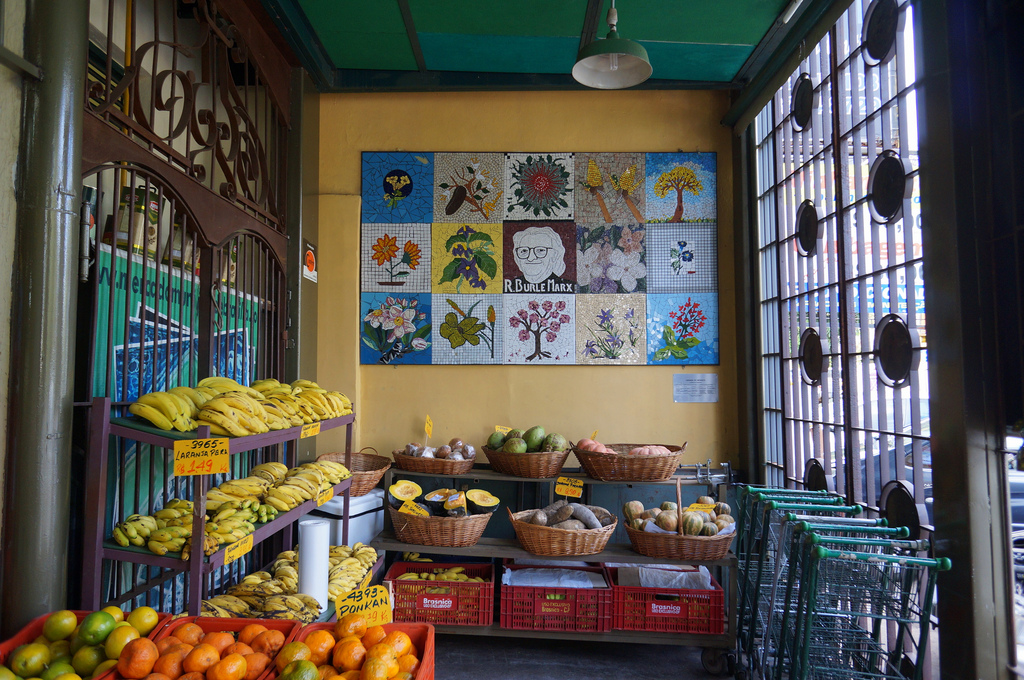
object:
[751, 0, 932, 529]
gate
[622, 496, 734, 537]
fruit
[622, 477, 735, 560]
basket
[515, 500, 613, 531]
fruit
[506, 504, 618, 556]
basket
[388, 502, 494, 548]
basket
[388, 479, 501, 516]
fruit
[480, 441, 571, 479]
basket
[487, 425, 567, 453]
fruit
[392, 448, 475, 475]
basket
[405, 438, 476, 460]
fruit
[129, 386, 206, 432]
bananas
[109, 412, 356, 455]
shelf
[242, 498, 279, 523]
bananas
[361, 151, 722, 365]
artwork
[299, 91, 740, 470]
yellow wall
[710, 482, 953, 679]
shopping carts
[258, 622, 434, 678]
basket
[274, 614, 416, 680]
orange fruit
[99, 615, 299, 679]
basket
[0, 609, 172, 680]
basket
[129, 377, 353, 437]
yellow bananas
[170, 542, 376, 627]
yellow bananas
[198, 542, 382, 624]
bottom shelf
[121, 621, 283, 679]
fruits